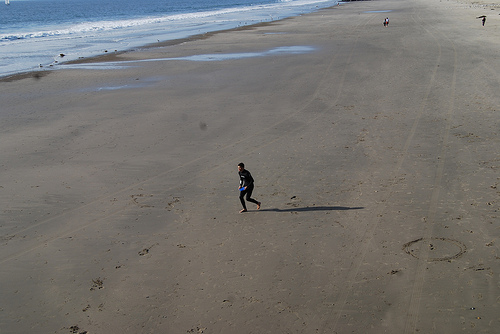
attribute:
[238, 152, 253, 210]
man — running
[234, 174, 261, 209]
wet suit — black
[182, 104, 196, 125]
sand — brown, wet